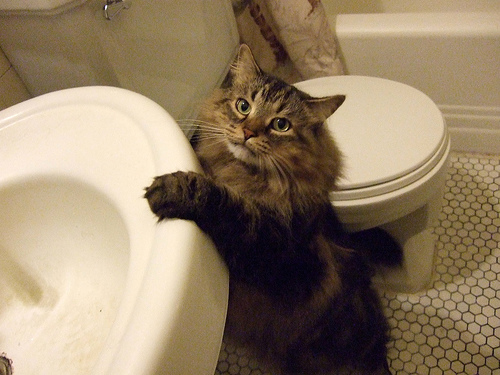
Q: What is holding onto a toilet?
A: Cat.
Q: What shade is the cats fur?
A: Brown.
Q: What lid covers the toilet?
A: The seat.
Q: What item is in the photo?
A: The sink.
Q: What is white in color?
A: The sink.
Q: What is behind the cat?
A: The toilet seat cover.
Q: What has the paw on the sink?
A: The cat.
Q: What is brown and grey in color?
A: The tabby cat.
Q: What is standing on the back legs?
A: The cat.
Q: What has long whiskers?
A: The cat.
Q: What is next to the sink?
A: The cat.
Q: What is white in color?
A: The toilet seat cover.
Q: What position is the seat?
A: Closed.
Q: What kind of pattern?
A: Hexagon.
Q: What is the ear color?
A: Brown.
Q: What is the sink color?
A: White.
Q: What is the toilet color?
A: White.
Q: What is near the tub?
A: Curtain.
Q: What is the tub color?
A: White.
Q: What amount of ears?
A: Two.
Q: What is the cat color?
A: Brown.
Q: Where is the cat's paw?
A: On the sink.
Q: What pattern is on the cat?
A: Stripes.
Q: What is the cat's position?
A: The cat is standing on its hind legs.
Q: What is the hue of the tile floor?
A: Black & white.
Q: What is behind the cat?
A: A white toilet.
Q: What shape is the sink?
A: The sink is round.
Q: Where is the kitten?
A: In the bathroom.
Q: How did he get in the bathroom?
A: His owner left the door open.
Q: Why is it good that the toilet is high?
A: Because the kitten cannot reach it.